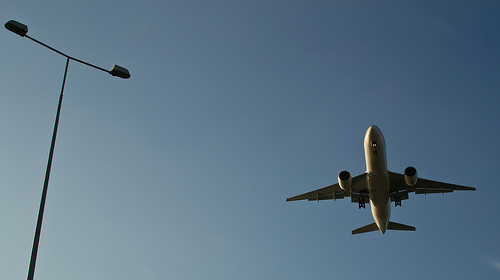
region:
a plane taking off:
[278, 114, 478, 251]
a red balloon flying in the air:
[462, 218, 478, 237]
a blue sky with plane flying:
[4, 3, 489, 262]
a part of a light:
[85, 40, 153, 110]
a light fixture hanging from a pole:
[0, 11, 136, 276]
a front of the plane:
[357, 115, 397, 168]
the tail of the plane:
[349, 216, 429, 243]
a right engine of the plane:
[400, 153, 419, 195]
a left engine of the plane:
[336, 162, 358, 203]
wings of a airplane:
[279, 153, 484, 210]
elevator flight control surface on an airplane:
[387, 226, 414, 231]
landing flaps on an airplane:
[413, 187, 454, 194]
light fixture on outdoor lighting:
[110, 59, 137, 81]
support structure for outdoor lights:
[11, 40, 103, 275]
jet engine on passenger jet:
[336, 168, 351, 194]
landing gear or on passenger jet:
[369, 140, 380, 155]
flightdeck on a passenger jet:
[362, 123, 384, 140]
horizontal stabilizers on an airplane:
[349, 216, 419, 242]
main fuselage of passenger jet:
[363, 139, 393, 216]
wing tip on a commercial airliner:
[284, 190, 309, 207]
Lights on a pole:
[3, 16, 138, 179]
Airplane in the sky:
[277, 102, 487, 256]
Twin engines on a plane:
[334, 159, 428, 199]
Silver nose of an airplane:
[350, 116, 404, 158]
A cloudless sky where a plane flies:
[167, 28, 490, 242]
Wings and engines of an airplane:
[276, 162, 484, 207]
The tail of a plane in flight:
[343, 213, 427, 248]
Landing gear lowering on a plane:
[351, 167, 408, 232]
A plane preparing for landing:
[0, 11, 495, 258]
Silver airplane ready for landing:
[276, 107, 488, 251]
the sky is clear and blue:
[242, 207, 262, 222]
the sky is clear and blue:
[214, 203, 239, 238]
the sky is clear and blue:
[191, 200, 214, 223]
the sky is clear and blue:
[228, 271, 247, 278]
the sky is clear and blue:
[208, 215, 228, 232]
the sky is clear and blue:
[233, 215, 247, 230]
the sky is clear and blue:
[205, 249, 227, 259]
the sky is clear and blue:
[214, 226, 239, 243]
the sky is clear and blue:
[218, 219, 234, 229]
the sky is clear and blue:
[239, 235, 257, 242]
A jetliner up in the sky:
[277, 109, 487, 251]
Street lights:
[0, 12, 145, 274]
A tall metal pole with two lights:
[3, 2, 155, 277]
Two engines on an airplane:
[325, 163, 425, 204]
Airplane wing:
[282, 166, 338, 212]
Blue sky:
[152, 10, 469, 119]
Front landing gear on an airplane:
[366, 135, 384, 152]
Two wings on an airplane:
[282, 162, 483, 207]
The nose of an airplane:
[358, 116, 395, 161]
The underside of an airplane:
[281, 112, 490, 245]